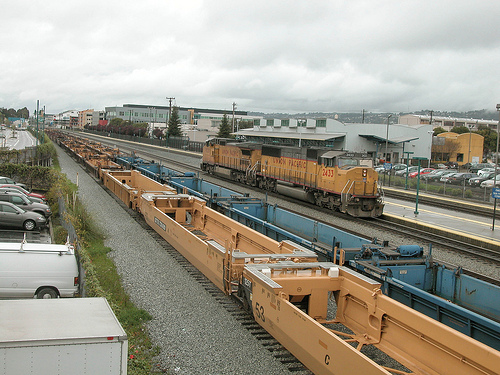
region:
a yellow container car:
[242, 262, 499, 374]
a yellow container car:
[139, 194, 317, 292]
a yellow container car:
[99, 170, 174, 212]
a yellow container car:
[70, 146, 100, 156]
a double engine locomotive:
[199, 132, 381, 217]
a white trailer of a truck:
[0, 294, 128, 374]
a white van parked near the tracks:
[0, 235, 80, 297]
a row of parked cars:
[0, 174, 47, 239]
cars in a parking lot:
[373, 160, 498, 189]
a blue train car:
[217, 198, 421, 254]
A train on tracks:
[185, 137, 431, 217]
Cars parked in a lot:
[0, 170, 129, 372]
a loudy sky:
[52, 22, 442, 73]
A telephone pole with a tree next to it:
[165, 95, 191, 149]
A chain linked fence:
[101, 132, 196, 151]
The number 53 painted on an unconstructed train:
[249, 299, 284, 323]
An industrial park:
[86, 94, 466, 148]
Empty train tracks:
[113, 130, 193, 160]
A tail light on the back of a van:
[70, 274, 85, 291]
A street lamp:
[373, 112, 396, 168]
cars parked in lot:
[377, 160, 488, 184]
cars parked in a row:
[5, 164, 45, 236]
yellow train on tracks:
[196, 132, 392, 218]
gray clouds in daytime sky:
[345, 26, 455, 98]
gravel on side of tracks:
[141, 256, 185, 309]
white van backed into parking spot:
[9, 237, 85, 299]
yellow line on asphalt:
[406, 202, 467, 219]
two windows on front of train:
[331, 153, 377, 169]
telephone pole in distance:
[162, 92, 180, 122]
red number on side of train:
[316, 166, 338, 181]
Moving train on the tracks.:
[195, 130, 387, 220]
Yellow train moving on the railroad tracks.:
[199, 145, 385, 219]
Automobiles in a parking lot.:
[0, 175, 53, 233]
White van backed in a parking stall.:
[1, 232, 78, 297]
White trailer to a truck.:
[0, 295, 129, 373]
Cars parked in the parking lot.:
[379, 154, 499, 191]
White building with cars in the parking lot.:
[232, 117, 498, 189]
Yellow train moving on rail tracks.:
[80, 125, 498, 260]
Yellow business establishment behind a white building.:
[433, 130, 484, 167]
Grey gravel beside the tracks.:
[135, 175, 305, 373]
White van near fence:
[8, 217, 110, 301]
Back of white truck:
[26, 291, 143, 361]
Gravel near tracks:
[87, 162, 171, 370]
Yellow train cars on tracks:
[185, 103, 367, 241]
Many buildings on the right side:
[108, 82, 429, 183]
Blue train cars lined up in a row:
[158, 165, 457, 296]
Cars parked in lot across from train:
[377, 153, 456, 195]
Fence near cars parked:
[44, 180, 91, 305]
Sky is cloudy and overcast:
[213, 73, 381, 120]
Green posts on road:
[403, 148, 423, 256]